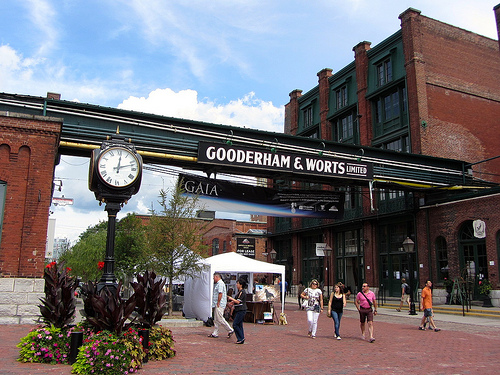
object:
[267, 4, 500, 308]
building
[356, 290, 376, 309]
pink shirt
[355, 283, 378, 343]
man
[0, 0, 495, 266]
sky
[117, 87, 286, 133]
cloud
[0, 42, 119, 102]
cloud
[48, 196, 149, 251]
cloud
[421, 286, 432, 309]
shirt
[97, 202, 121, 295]
pole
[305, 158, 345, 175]
word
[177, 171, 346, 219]
sign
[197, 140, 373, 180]
sign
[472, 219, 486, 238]
sign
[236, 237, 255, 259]
sign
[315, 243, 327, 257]
sign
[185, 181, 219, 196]
gaia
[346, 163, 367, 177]
united word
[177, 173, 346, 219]
banner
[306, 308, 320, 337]
white pants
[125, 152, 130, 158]
numerals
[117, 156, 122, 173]
hands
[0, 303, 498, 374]
side walk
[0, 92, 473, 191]
bridge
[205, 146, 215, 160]
letter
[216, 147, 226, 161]
letter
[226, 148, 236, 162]
letter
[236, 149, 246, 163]
letter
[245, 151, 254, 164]
letter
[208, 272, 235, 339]
man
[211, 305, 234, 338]
pants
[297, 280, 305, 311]
people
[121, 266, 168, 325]
plants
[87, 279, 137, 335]
plants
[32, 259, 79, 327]
plants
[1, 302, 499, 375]
tile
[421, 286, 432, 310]
orange top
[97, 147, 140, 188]
clock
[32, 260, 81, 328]
shrub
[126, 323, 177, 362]
shrub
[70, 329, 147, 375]
shrub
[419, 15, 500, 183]
wall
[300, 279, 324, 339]
person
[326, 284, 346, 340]
person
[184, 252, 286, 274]
roof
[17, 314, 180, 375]
flowers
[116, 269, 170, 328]
shrub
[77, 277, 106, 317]
shrub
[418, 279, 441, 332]
man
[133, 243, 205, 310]
tent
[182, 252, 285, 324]
tent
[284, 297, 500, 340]
street